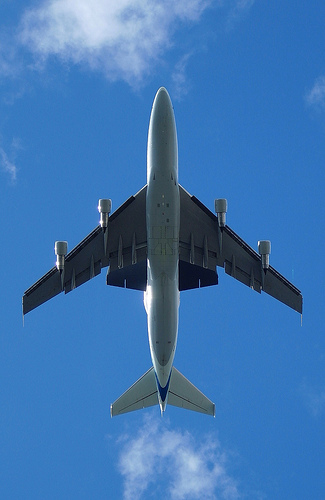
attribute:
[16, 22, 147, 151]
sky — blue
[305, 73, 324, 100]
clouds — white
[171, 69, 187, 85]
clouds — white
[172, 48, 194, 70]
clouds — white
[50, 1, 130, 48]
clouds — white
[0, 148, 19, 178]
clouds — white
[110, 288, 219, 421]
tail — blue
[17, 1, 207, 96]
clouds — white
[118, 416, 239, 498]
clouds — white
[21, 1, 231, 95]
clouds — white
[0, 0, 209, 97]
cloud — white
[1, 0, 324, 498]
sky — blue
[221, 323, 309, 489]
sky — blue